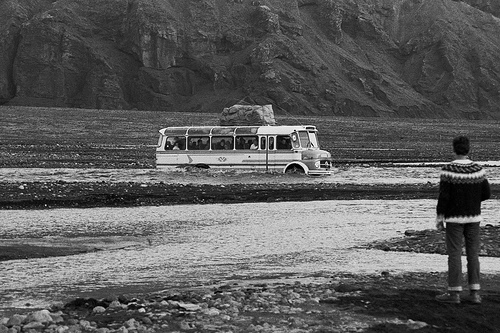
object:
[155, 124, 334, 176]
bus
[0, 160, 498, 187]
water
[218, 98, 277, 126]
cargo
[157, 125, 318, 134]
bus' roof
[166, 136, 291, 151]
people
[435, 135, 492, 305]
man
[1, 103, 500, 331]
ground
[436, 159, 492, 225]
sweater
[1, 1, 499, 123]
hill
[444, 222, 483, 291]
pants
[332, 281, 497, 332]
dirt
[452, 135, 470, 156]
hair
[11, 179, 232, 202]
rocks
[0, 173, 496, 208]
dirt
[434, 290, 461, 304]
shoe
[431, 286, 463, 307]
foot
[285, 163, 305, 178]
tire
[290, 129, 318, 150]
windshield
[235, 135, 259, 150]
window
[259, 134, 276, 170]
door